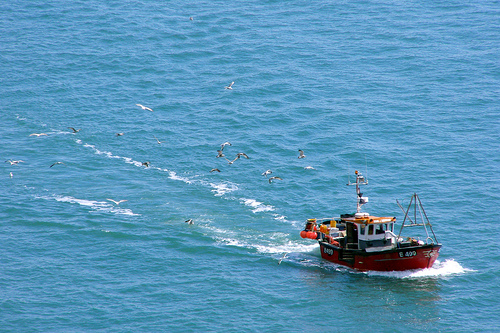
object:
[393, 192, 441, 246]
tri-pod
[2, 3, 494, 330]
water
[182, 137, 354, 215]
buoys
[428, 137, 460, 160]
ground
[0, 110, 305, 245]
trail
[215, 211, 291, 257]
seagulls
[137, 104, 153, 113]
bird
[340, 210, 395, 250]
bridge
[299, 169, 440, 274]
boat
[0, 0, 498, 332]
ocean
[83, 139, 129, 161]
ripples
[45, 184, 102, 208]
ripples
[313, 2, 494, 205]
water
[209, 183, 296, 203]
seagulls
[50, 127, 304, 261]
wake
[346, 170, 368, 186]
area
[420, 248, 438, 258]
bow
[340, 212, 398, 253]
cabin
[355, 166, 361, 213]
pole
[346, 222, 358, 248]
window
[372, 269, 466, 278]
water splashing